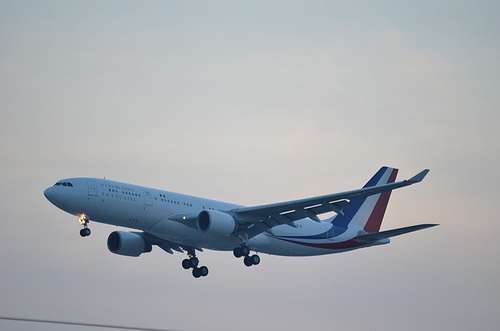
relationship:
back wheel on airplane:
[239, 258, 267, 268] [44, 165, 442, 278]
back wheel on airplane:
[231, 245, 251, 258] [44, 165, 442, 278]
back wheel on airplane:
[187, 263, 211, 281] [44, 165, 442, 278]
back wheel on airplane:
[180, 253, 197, 269] [44, 165, 442, 278]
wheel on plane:
[79, 227, 92, 240] [3, 150, 448, 276]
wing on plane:
[358, 221, 437, 242] [61, 135, 458, 255]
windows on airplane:
[106, 186, 193, 206] [44, 165, 442, 278]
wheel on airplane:
[79, 227, 91, 238] [38, 155, 452, 287]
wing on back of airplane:
[327, 165, 400, 233] [40, 161, 442, 282]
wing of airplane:
[358, 221, 437, 242] [27, 150, 447, 277]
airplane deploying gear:
[44, 165, 442, 278] [69, 212, 281, 282]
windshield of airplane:
[48, 178, 74, 188] [44, 165, 442, 278]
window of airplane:
[55, 181, 74, 186] [44, 165, 442, 278]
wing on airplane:
[235, 165, 432, 221] [40, 161, 442, 282]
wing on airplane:
[123, 225, 159, 249] [40, 161, 442, 282]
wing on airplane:
[361, 221, 437, 242] [40, 161, 442, 282]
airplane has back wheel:
[40, 161, 442, 282] [243, 254, 261, 267]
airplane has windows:
[44, 165, 442, 278] [115, 186, 239, 221]